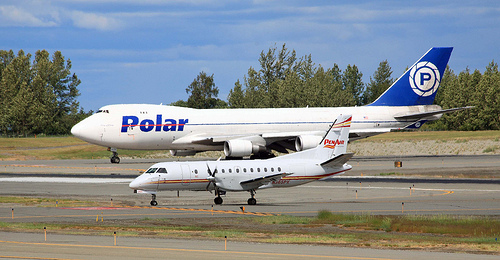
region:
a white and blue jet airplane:
[67, 45, 476, 162]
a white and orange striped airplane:
[125, 112, 357, 207]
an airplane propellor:
[202, 161, 222, 195]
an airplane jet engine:
[220, 137, 266, 154]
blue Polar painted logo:
[120, 115, 190, 134]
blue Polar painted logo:
[409, 61, 440, 96]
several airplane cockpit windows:
[95, 108, 110, 113]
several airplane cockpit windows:
[144, 167, 166, 173]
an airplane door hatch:
[180, 163, 190, 185]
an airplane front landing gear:
[148, 198, 156, 206]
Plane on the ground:
[129, 110, 364, 212]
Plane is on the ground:
[125, 110, 353, 210]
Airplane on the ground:
[71, 38, 479, 163]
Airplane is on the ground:
[66, 40, 477, 165]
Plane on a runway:
[65, 35, 480, 168]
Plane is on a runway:
[62, 37, 481, 169]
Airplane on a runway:
[64, 40, 479, 165]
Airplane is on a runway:
[70, 42, 480, 169]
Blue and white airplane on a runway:
[67, 36, 479, 165]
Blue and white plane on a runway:
[68, 39, 484, 166]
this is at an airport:
[20, 17, 470, 239]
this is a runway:
[29, 68, 391, 224]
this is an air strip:
[26, 154, 358, 254]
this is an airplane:
[89, 83, 416, 166]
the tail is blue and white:
[373, 23, 472, 115]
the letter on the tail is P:
[404, 61, 436, 106]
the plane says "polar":
[95, 108, 196, 129]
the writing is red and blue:
[106, 78, 208, 159]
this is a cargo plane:
[91, 92, 266, 125]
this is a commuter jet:
[145, 145, 352, 190]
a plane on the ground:
[121, 131, 376, 256]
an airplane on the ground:
[79, 77, 400, 255]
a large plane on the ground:
[87, 85, 292, 214]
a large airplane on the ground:
[51, 75, 239, 129]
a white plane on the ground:
[65, 92, 392, 239]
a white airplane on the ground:
[85, 59, 392, 206]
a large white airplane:
[77, 56, 386, 231]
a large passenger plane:
[46, 74, 280, 197]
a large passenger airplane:
[86, 64, 312, 204]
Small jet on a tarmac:
[107, 116, 354, 196]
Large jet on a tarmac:
[70, 47, 456, 159]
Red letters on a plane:
[325, 137, 345, 148]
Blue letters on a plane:
[119, 109, 189, 134]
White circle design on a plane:
[410, 62, 441, 94]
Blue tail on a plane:
[378, 44, 454, 102]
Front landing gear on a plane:
[149, 194, 161, 208]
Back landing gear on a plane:
[212, 195, 264, 204]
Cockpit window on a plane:
[146, 166, 167, 173]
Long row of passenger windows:
[202, 165, 280, 172]